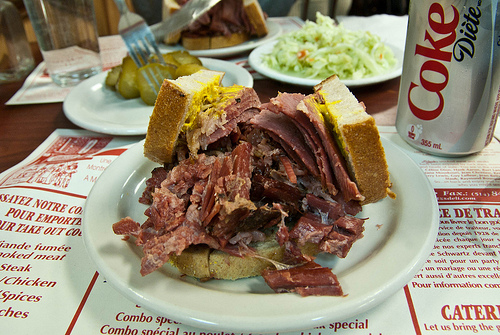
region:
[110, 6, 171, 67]
fork stabbed in food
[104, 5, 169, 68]
silver fork stabbed in food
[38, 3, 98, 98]
clear glass holding water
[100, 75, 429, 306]
plate of food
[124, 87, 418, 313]
a sandwich on a plate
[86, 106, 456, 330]
food on a white circular plate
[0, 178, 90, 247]
words written with red ink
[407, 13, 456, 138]
word written in red ink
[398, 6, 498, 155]
a can of soda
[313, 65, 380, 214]
bread with mustard on it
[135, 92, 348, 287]
pinle of meat on bread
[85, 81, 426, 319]
sandwich on white plate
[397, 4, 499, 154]
red and black on silver can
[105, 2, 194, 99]
fork in pile of pickes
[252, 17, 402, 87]
shredded lettuce on plate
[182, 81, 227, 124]
yellow mustard on white bread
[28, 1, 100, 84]
water in clear glass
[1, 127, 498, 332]
white mat with red words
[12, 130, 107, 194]
illustration on corner of mat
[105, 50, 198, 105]
slices of green pickles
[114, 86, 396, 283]
A large sandwich.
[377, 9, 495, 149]
A can of diet coke.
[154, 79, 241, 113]
The bread has mustard.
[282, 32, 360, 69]
Cole slaw on a plate.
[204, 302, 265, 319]
The plate is white.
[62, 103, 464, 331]
The plate is round.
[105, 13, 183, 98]
A fork is on the plate.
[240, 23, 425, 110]
The plate is smaller.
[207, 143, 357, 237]
Corned beef in a sandwich.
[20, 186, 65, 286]
A menu on top of the table.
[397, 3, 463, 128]
A red "Coke" sign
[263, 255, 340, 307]
A small piece of bacon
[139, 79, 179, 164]
A small piece of bread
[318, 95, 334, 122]
Some Mustard paste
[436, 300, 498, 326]
The word "Cater" in Red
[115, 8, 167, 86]
The silver portion of the fork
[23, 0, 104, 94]
A tall glass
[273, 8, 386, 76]
A set of vegetables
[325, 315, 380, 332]
The word "Special"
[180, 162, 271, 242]
A portion of "bacon"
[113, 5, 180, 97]
Fork going through a pickle slice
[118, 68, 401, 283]
Corned beef sandwich falling apart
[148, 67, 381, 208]
Lots of mustard on this sandwich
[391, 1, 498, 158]
Can of diet coke on the table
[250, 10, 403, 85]
Plate of coleslaw as a side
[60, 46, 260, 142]
Plate of pickle slices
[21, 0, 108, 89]
Glass of water on the table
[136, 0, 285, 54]
A sandwich for the other person dining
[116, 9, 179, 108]
Using a four pronged fork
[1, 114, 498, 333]
Paper place mat with red lettering